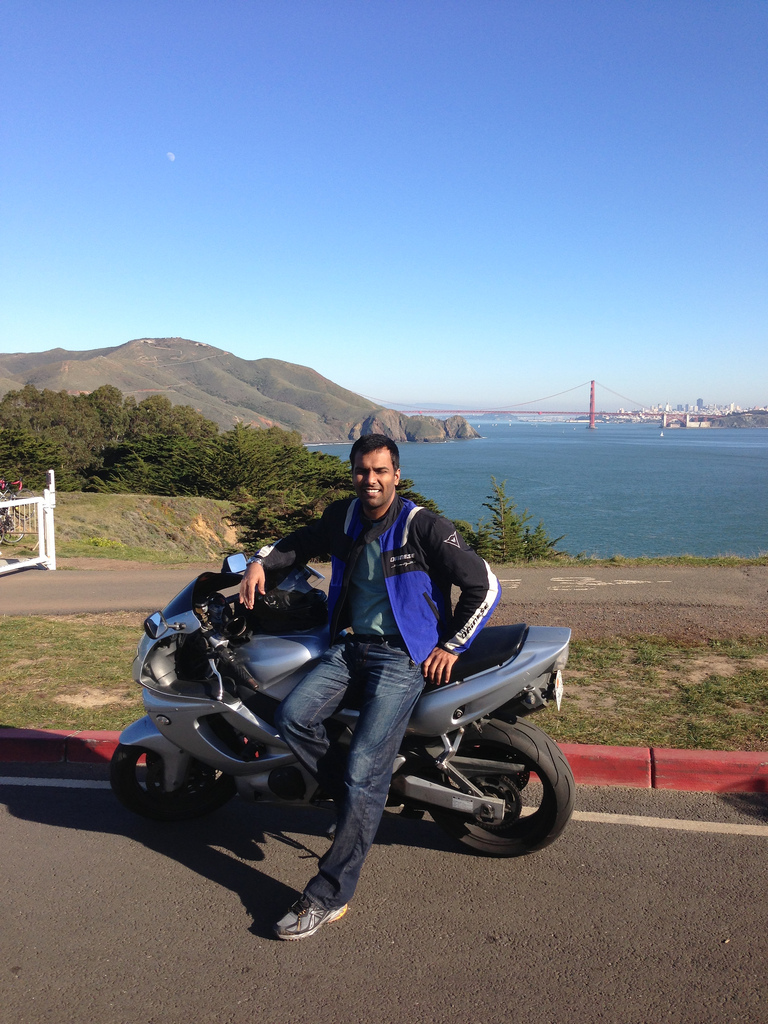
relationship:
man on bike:
[246, 409, 511, 963] [112, 552, 576, 859]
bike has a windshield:
[97, 542, 595, 870] [116, 546, 247, 638]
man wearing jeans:
[243, 434, 499, 941] [281, 641, 431, 897]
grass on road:
[605, 650, 736, 721] [483, 855, 713, 968]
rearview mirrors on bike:
[212, 551, 253, 574] [120, 580, 309, 788]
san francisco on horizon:
[591, 398, 766, 437] [409, 398, 758, 428]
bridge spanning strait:
[394, 381, 711, 429] [299, 423, 761, 555]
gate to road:
[5, 472, 62, 572] [37, 546, 171, 597]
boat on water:
[642, 409, 688, 445] [566, 462, 698, 537]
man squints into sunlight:
[243, 434, 499, 941] [342, 148, 744, 487]